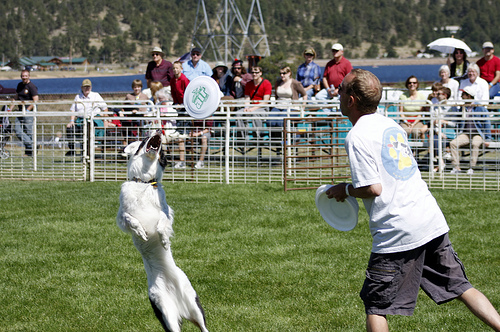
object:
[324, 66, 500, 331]
man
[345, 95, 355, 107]
ear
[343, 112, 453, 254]
shirt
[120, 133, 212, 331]
dog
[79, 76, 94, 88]
hat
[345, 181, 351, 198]
band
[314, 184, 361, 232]
white frisbees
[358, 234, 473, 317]
cargo shorts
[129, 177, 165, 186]
collar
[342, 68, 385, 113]
hair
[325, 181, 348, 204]
hand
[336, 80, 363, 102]
sunglasses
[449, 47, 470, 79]
woman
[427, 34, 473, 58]
umbrella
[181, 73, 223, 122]
frisbee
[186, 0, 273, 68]
pylon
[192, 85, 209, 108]
print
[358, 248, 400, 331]
leg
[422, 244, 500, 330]
leg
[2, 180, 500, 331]
grass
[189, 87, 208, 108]
text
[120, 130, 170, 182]
head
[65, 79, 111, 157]
man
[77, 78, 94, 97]
head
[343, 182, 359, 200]
wrist